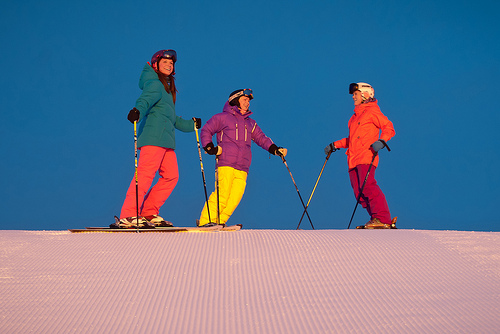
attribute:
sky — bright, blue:
[1, 1, 499, 230]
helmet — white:
[347, 82, 375, 103]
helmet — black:
[227, 87, 254, 108]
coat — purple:
[200, 101, 282, 176]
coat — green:
[133, 61, 196, 152]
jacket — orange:
[333, 99, 396, 173]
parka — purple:
[200, 101, 282, 175]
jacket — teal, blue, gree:
[131, 61, 196, 151]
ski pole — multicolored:
[132, 117, 139, 231]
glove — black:
[126, 108, 140, 124]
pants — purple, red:
[347, 163, 394, 226]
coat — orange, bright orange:
[332, 100, 396, 173]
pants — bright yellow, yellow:
[199, 166, 247, 226]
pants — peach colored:
[118, 145, 180, 220]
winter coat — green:
[133, 61, 194, 152]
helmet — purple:
[150, 49, 177, 65]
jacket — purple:
[200, 101, 279, 175]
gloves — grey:
[324, 142, 387, 154]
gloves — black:
[126, 107, 202, 129]